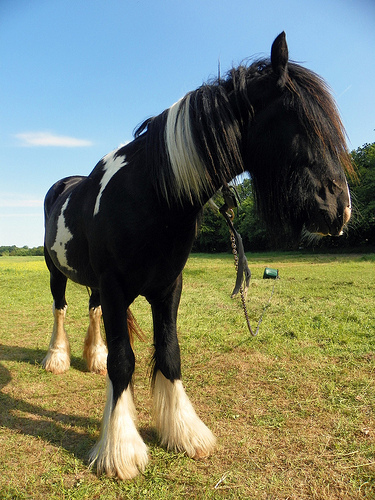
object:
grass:
[365, 255, 373, 269]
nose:
[341, 195, 353, 224]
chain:
[241, 289, 252, 333]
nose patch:
[343, 196, 352, 220]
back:
[46, 138, 133, 196]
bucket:
[263, 267, 279, 279]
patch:
[71, 196, 80, 217]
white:
[55, 228, 64, 236]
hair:
[163, 95, 205, 200]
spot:
[50, 197, 75, 277]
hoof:
[46, 335, 70, 374]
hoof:
[83, 337, 113, 371]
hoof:
[95, 428, 152, 477]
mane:
[197, 75, 255, 110]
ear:
[272, 30, 289, 68]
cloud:
[11, 126, 27, 139]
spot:
[90, 150, 127, 215]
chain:
[196, 104, 227, 188]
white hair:
[53, 348, 61, 358]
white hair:
[95, 350, 104, 358]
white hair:
[118, 433, 131, 446]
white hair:
[180, 408, 187, 427]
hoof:
[168, 410, 223, 456]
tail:
[87, 286, 148, 347]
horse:
[42, 30, 351, 478]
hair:
[287, 63, 365, 185]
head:
[249, 30, 353, 237]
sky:
[1, 2, 373, 50]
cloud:
[68, 138, 83, 148]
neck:
[171, 67, 247, 223]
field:
[2, 253, 370, 495]